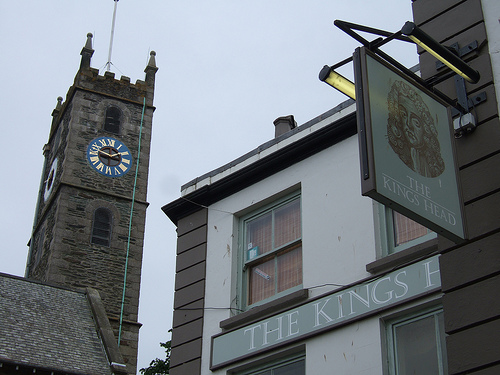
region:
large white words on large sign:
[217, 291, 428, 341]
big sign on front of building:
[190, 274, 437, 343]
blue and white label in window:
[236, 239, 278, 271]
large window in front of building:
[213, 188, 346, 322]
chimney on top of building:
[269, 103, 304, 148]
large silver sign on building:
[331, 38, 486, 256]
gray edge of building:
[65, 270, 139, 370]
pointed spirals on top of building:
[72, 33, 198, 83]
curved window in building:
[76, 192, 129, 264]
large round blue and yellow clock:
[86, 138, 151, 193]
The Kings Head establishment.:
[160, 18, 499, 373]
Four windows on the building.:
[214, 182, 446, 374]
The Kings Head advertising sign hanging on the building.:
[319, 18, 487, 244]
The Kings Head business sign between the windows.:
[208, 252, 440, 372]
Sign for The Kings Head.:
[206, 255, 441, 372]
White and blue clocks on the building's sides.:
[40, 132, 134, 202]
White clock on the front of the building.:
[37, 146, 67, 197]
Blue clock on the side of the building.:
[84, 135, 134, 177]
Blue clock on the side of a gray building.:
[67, 103, 143, 216]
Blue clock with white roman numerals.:
[85, 135, 132, 178]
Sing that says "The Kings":
[208, 244, 498, 346]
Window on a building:
[212, 195, 309, 312]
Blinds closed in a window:
[224, 194, 321, 336]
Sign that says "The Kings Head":
[355, 46, 471, 225]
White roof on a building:
[160, 68, 373, 211]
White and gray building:
[152, 154, 387, 374]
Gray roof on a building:
[10, 271, 132, 373]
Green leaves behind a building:
[145, 321, 184, 370]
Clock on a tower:
[78, 129, 142, 191]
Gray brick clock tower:
[39, 143, 178, 288]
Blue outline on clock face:
[69, 132, 161, 209]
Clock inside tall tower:
[66, 90, 126, 273]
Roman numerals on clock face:
[75, 135, 148, 192]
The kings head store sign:
[350, 70, 499, 255]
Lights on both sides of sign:
[321, 35, 475, 133]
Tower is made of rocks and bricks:
[36, 70, 142, 326]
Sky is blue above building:
[188, 65, 244, 115]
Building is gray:
[169, 212, 204, 370]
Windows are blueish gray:
[233, 212, 307, 296]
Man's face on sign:
[381, 70, 438, 190]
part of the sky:
[172, 37, 250, 99]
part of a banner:
[392, 111, 454, 178]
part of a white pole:
[109, 0, 120, 62]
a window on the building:
[226, 197, 307, 287]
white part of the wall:
[323, 202, 367, 247]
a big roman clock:
[91, 137, 132, 179]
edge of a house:
[156, 280, 188, 333]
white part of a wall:
[305, 189, 332, 246]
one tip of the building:
[143, 41, 153, 92]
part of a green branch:
[151, 356, 164, 372]